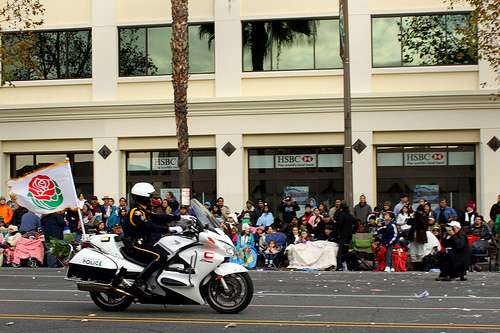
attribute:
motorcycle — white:
[66, 197, 255, 312]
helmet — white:
[130, 181, 157, 206]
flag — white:
[7, 157, 88, 240]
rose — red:
[27, 174, 57, 201]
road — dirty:
[1, 266, 498, 332]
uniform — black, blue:
[120, 207, 197, 295]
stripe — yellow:
[133, 243, 159, 261]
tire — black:
[203, 268, 255, 316]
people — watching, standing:
[206, 194, 499, 271]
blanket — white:
[286, 240, 337, 273]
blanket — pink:
[12, 235, 45, 265]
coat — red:
[394, 245, 409, 272]